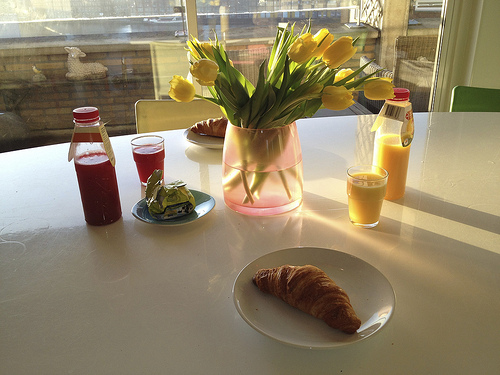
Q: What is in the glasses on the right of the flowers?
A: Orange juice.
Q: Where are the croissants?
A: In the plates.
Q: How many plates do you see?
A: Two.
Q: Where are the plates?
A: On the table.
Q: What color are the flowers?
A: Yellow.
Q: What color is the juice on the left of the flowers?
A: Red.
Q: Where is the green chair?
A: On the right.